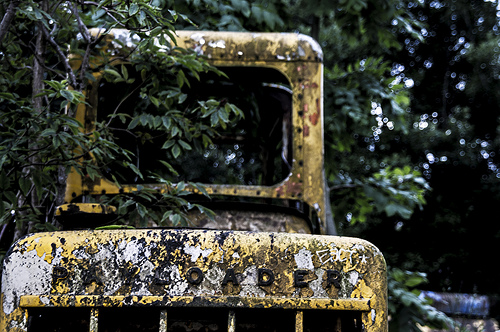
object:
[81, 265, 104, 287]
writing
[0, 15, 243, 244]
tree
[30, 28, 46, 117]
branch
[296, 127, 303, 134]
bolt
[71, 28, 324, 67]
roof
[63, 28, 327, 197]
cab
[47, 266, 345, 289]
logo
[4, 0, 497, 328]
forest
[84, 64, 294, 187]
window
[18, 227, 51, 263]
paint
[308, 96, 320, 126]
rust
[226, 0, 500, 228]
tree branches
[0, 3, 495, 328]
jungle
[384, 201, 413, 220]
leaves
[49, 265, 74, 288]
letters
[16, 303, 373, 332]
grill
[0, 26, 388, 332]
payloader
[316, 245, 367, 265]
graffiti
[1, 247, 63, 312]
area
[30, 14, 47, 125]
tree branch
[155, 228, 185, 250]
marks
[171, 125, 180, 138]
leaves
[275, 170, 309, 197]
area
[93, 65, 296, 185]
window opening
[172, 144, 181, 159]
leaves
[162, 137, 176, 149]
leaves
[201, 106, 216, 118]
leaves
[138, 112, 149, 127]
leaves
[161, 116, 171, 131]
leaves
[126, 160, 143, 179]
leaves